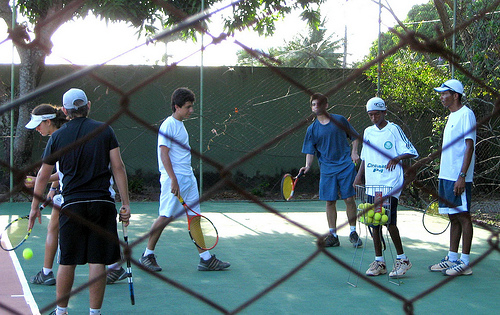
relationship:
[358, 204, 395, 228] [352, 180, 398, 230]
balls in basket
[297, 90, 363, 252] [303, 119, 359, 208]
boy in blue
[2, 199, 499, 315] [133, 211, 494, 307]
ground has shadow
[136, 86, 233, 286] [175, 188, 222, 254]
man holding racket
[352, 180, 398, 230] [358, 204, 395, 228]
container holding balls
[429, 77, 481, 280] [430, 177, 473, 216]
man wearing shorts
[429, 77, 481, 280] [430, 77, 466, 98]
man wearing cap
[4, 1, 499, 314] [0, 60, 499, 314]
fence surrounds court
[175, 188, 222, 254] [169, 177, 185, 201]
racket in hand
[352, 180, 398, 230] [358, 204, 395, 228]
container with balls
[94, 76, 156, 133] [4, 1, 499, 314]
link in fence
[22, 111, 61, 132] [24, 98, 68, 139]
visor on head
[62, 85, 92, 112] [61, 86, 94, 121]
hat on head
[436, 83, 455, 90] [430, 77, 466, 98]
glasses on hat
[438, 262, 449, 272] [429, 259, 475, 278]
stripes on shoes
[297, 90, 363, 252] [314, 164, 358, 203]
person with shorts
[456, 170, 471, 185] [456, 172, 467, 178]
wrist has watch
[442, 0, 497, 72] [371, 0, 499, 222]
tree behind fence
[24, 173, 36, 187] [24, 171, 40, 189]
ball in hand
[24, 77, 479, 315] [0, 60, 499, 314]
people on court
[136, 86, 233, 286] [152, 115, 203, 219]
man wearing white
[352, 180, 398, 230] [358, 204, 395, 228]
basket holding balls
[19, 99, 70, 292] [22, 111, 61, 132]
woman wearing visor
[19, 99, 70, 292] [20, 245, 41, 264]
woman bouncing ball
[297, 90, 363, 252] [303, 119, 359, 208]
man wearing blue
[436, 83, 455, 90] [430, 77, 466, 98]
sunglasses on hat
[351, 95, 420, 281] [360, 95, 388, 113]
person wearing hat